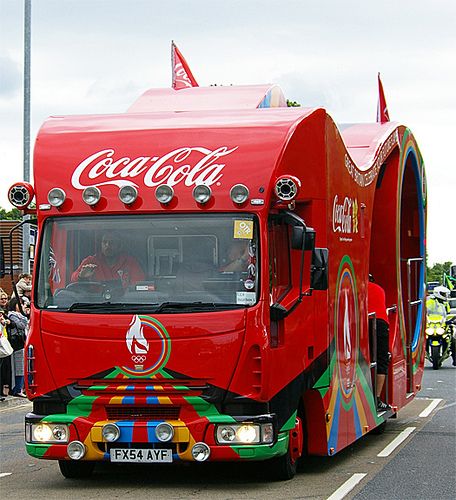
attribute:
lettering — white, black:
[118, 149, 215, 175]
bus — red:
[232, 118, 334, 171]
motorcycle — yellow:
[428, 319, 453, 337]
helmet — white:
[433, 284, 448, 291]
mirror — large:
[310, 245, 327, 297]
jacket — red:
[118, 264, 139, 274]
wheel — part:
[281, 434, 317, 459]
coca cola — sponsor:
[69, 145, 238, 177]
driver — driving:
[74, 227, 147, 290]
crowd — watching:
[1, 306, 35, 398]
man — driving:
[415, 266, 451, 323]